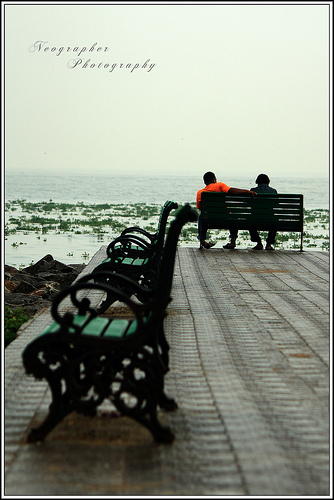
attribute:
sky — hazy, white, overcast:
[9, 8, 329, 161]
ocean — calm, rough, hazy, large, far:
[6, 165, 321, 219]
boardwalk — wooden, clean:
[2, 247, 327, 496]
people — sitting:
[197, 171, 281, 195]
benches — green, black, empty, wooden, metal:
[34, 197, 190, 446]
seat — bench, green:
[43, 311, 136, 348]